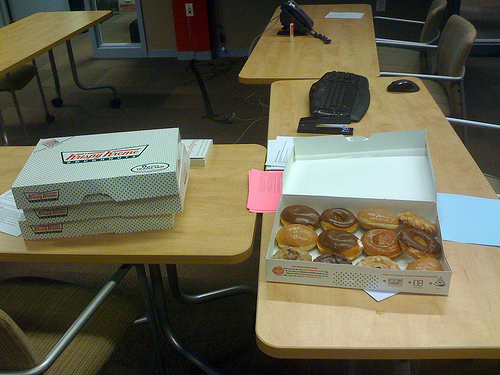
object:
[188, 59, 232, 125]
tape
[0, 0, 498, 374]
floor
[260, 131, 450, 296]
box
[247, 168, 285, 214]
paper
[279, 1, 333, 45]
phone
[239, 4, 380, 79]
table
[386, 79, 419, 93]
mouse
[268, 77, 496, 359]
table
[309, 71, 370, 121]
keyboard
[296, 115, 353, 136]
stapler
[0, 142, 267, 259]
table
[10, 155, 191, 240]
box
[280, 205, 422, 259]
doughnut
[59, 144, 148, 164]
logo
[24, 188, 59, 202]
logo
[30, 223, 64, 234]
logo